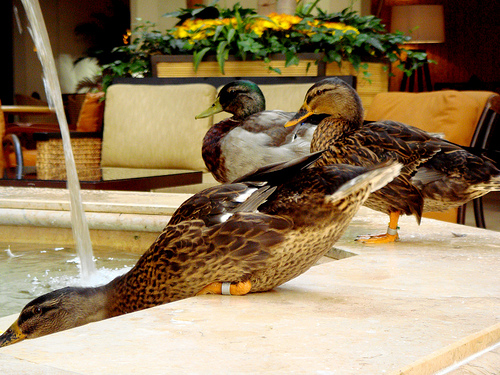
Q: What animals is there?
A: Ducks.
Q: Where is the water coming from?
A: Faucet.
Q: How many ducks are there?
A: 3.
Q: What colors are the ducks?
A: Brown.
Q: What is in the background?
A: Furniture.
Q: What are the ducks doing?
A: Standing.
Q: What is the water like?
A: Streaming.